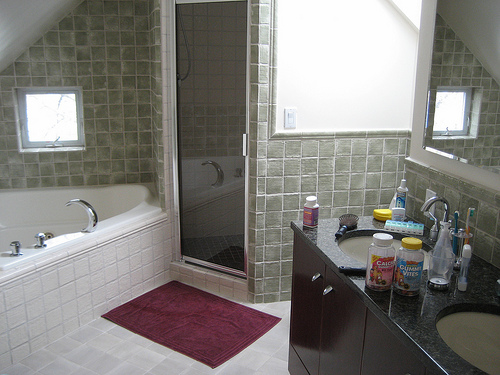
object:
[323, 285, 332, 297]
knobs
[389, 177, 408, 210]
tube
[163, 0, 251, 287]
door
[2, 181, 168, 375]
tub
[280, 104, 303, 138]
outlet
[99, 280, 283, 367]
mat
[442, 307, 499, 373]
sink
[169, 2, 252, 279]
shower door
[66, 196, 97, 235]
tub controls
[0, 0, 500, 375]
bathroom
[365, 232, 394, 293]
bottle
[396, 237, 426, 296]
bottles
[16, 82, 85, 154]
window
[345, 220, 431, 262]
sink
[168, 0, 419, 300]
shower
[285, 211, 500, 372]
cabinet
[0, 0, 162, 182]
wall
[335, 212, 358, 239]
brush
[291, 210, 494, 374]
counter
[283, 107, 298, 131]
light switch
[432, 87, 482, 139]
window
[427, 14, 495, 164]
wall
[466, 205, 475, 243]
toothbrushes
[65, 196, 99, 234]
faucet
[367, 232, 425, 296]
vitamins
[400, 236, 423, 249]
top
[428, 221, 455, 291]
bottles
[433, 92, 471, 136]
mirror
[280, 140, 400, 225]
wall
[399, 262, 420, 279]
label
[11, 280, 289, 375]
floor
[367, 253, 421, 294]
vanity